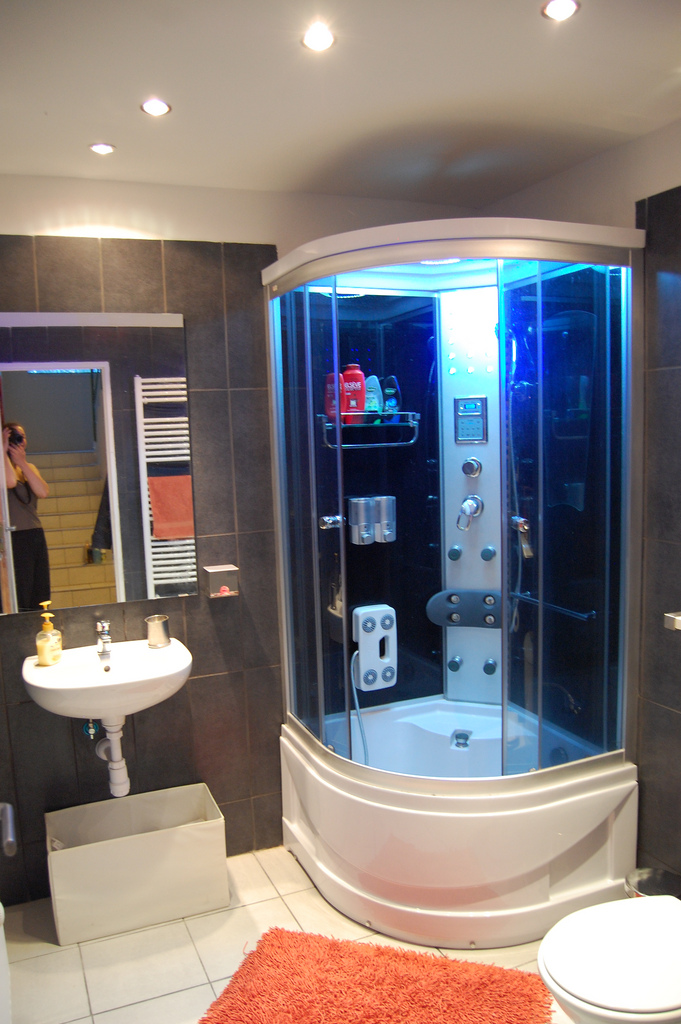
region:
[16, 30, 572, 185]
Ceiling is white color.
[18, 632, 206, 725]
Sink is white color.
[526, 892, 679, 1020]
Toilet is white color.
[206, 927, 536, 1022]
mat is orange color.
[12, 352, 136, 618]
Mirror is fixed to the wall.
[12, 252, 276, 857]
Wall is black color.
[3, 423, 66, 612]
Woman is taking photo.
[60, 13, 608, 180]
Light is on.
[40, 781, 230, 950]
A large white tub sitting under a sink.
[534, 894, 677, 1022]
A white toilet bowl with a white lid.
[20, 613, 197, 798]
A white sink mounted to a wall.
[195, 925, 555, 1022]
A pink rug sitting on a bathroom floor.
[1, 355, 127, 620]
A large rectangular mirror with a shiny surface.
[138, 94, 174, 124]
A light mounted in a ceiling.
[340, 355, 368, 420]
A bottle or shower gel in a shower.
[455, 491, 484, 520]
A water control knob in a shower.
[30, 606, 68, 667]
A large bottle of soap.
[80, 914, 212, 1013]
A square tile on a bathroom floor.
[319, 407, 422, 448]
silver shelf on the shower wall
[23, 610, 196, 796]
white sink in the ballroom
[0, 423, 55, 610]
reflection of a person taking the picture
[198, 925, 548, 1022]
pink rug on the bathroom floor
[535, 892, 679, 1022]
white toilet in the bathroom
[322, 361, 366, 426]
red and white shampoo bottles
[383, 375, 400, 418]
black and white shampoo bottle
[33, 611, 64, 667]
soap on the bathroom sink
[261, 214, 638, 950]
shower in the corner of the bathroom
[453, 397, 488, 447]
controls for the shower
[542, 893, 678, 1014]
white toilet top of toilet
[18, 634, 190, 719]
white sink against the wall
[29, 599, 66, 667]
pump bottle sitting on the sink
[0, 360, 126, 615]
mirror on the wall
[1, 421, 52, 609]
woman in a black dress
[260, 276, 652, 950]
hi-tech shower in the corner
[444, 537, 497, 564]
knobs for water control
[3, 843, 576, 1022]
white tiled floor in the bathroom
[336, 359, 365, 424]
red bottle on the shelf in the shower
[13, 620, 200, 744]
A white sink on the wall.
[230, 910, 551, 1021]
An orange rug on the floor.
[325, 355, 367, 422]
The red bottle on the shelf.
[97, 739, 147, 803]
White pipes hanging from the sink.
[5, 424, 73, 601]
People in the mirror.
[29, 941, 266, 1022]
The tiles are white.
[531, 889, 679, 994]
The toilet seat lid is down.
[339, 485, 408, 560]
Dispensers in the shower.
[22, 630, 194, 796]
white sink on a wall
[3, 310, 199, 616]
bathroom wall mirror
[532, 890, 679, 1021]
white lid of a toilet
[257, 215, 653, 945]
white shower in a bathroom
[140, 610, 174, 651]
gold metal cup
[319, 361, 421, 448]
shampoo in a caddy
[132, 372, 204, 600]
towel rack with an orange towel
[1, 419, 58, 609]
woman taking a photo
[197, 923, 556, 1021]
thick orange bath rug on floor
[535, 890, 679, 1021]
clean white toilet with seat down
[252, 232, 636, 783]
blue glass doors on shower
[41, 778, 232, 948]
white linen basket beneath sink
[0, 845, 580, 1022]
beige tiles covering bathroom floor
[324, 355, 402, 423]
soap and body wash on top shelf of shower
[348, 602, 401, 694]
white pad with blue jet circles